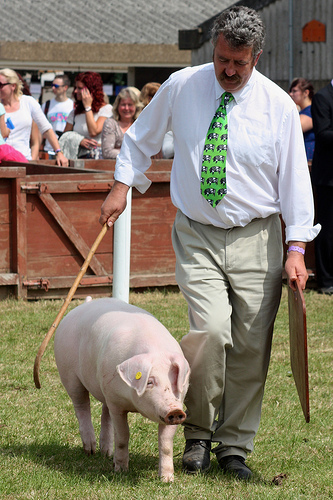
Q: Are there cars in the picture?
A: No, there are no cars.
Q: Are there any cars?
A: No, there are no cars.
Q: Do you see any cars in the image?
A: No, there are no cars.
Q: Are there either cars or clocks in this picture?
A: No, there are no cars or clocks.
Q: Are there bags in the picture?
A: No, there are no bags.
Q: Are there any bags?
A: No, there are no bags.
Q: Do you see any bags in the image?
A: No, there are no bags.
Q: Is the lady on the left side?
A: Yes, the lady is on the left of the image.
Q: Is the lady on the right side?
A: No, the lady is on the left of the image.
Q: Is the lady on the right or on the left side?
A: The lady is on the left of the image.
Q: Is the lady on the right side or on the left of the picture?
A: The lady is on the left of the image.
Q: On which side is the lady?
A: The lady is on the left of the image.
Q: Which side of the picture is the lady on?
A: The lady is on the left of the image.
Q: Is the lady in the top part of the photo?
A: Yes, the lady is in the top of the image.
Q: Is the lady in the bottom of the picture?
A: No, the lady is in the top of the image.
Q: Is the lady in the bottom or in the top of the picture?
A: The lady is in the top of the image.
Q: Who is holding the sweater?
A: The lady is holding the sweater.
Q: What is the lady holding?
A: The lady is holding the sweater.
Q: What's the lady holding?
A: The lady is holding the sweater.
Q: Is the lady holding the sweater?
A: Yes, the lady is holding the sweater.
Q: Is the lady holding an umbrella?
A: No, the lady is holding the sweater.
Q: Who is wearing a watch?
A: The lady is wearing a watch.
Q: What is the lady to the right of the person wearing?
A: The lady is wearing a watch.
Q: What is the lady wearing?
A: The lady is wearing a watch.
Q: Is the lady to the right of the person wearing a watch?
A: Yes, the lady is wearing a watch.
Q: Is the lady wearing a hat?
A: No, the lady is wearing a watch.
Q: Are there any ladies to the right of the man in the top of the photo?
A: Yes, there is a lady to the right of the man.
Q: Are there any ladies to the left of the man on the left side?
A: No, the lady is to the right of the man.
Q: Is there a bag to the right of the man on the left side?
A: No, there is a lady to the right of the man.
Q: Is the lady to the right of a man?
A: Yes, the lady is to the right of a man.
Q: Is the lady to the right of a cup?
A: No, the lady is to the right of a man.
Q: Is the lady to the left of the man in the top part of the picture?
A: No, the lady is to the right of the man.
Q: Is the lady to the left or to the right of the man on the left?
A: The lady is to the right of the man.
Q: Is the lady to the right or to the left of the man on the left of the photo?
A: The lady is to the right of the man.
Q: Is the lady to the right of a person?
A: Yes, the lady is to the right of a person.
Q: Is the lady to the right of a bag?
A: No, the lady is to the right of a person.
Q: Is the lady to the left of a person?
A: No, the lady is to the right of a person.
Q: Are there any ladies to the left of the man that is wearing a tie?
A: Yes, there is a lady to the left of the man.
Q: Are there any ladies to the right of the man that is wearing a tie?
A: No, the lady is to the left of the man.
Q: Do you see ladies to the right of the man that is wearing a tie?
A: No, the lady is to the left of the man.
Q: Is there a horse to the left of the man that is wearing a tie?
A: No, there is a lady to the left of the man.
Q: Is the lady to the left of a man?
A: Yes, the lady is to the left of a man.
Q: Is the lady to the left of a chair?
A: No, the lady is to the left of a man.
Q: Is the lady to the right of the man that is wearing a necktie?
A: No, the lady is to the left of the man.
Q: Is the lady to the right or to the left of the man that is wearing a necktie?
A: The lady is to the left of the man.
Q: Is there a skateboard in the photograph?
A: No, there are no skateboards.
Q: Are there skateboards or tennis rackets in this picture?
A: No, there are no skateboards or tennis rackets.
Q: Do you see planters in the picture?
A: No, there are no planters.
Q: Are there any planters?
A: No, there are no planters.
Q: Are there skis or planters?
A: No, there are no planters or skis.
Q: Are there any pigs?
A: Yes, there is a pig.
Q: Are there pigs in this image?
A: Yes, there is a pig.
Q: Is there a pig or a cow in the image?
A: Yes, there is a pig.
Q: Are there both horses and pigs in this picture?
A: No, there is a pig but no horses.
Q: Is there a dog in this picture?
A: No, there are no dogs.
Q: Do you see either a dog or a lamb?
A: No, there are no dogs or lambs.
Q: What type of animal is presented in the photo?
A: The animal is a pig.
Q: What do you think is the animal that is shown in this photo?
A: The animal is a pig.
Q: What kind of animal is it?
A: The animal is a pig.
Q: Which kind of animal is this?
A: That is a pig.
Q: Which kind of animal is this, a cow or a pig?
A: That is a pig.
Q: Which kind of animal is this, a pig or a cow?
A: That is a pig.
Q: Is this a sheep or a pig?
A: This is a pig.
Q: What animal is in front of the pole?
A: The pig is in front of the pole.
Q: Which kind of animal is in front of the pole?
A: The animal is a pig.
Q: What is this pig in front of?
A: The pig is in front of the pole.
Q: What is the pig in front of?
A: The pig is in front of the pole.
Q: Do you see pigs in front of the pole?
A: Yes, there is a pig in front of the pole.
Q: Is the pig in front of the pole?
A: Yes, the pig is in front of the pole.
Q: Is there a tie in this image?
A: Yes, there is a tie.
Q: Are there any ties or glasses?
A: Yes, there is a tie.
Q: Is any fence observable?
A: Yes, there is a fence.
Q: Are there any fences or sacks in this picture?
A: Yes, there is a fence.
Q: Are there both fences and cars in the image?
A: No, there is a fence but no cars.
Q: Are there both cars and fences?
A: No, there is a fence but no cars.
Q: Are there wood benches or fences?
A: Yes, there is a wood fence.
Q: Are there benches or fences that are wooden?
A: Yes, the fence is wooden.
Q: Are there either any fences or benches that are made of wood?
A: Yes, the fence is made of wood.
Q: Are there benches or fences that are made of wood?
A: Yes, the fence is made of wood.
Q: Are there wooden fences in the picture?
A: Yes, there is a wood fence.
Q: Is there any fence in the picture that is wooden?
A: Yes, there is a fence that is wooden.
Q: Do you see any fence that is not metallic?
A: Yes, there is a wooden fence.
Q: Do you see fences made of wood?
A: Yes, there is a fence that is made of wood.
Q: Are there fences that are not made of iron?
A: Yes, there is a fence that is made of wood.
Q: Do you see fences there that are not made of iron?
A: Yes, there is a fence that is made of wood.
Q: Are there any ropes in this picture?
A: No, there are no ropes.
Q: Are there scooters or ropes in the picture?
A: No, there are no ropes or scooters.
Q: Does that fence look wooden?
A: Yes, the fence is wooden.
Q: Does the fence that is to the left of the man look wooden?
A: Yes, the fence is wooden.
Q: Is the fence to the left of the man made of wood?
A: Yes, the fence is made of wood.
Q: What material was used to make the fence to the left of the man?
A: The fence is made of wood.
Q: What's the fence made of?
A: The fence is made of wood.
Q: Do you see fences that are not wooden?
A: No, there is a fence but it is wooden.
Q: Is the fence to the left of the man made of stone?
A: No, the fence is made of wood.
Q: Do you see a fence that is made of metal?
A: No, there is a fence but it is made of wood.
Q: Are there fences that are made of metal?
A: No, there is a fence but it is made of wood.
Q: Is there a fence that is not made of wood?
A: No, there is a fence but it is made of wood.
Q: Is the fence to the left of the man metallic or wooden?
A: The fence is wooden.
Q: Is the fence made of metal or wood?
A: The fence is made of wood.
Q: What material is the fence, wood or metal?
A: The fence is made of wood.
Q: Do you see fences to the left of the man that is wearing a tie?
A: Yes, there is a fence to the left of the man.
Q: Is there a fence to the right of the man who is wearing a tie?
A: No, the fence is to the left of the man.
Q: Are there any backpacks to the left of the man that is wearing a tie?
A: No, there is a fence to the left of the man.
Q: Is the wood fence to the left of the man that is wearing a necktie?
A: Yes, the fence is to the left of the man.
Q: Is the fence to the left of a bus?
A: No, the fence is to the left of the man.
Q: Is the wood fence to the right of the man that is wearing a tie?
A: No, the fence is to the left of the man.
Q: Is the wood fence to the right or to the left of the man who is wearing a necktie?
A: The fence is to the left of the man.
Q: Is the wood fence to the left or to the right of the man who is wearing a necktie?
A: The fence is to the left of the man.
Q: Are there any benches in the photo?
A: No, there are no benches.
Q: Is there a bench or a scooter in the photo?
A: No, there are no benches or scooters.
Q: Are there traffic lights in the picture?
A: No, there are no traffic lights.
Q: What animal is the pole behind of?
A: The pole is behind the pig.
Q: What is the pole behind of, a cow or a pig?
A: The pole is behind a pig.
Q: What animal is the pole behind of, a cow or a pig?
A: The pole is behind a pig.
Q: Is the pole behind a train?
A: No, the pole is behind a pig.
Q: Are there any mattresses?
A: No, there are no mattresses.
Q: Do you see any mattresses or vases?
A: No, there are no mattresses or vases.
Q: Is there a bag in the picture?
A: No, there are no bags.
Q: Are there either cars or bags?
A: No, there are no bags or cars.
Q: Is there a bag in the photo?
A: No, there are no bags.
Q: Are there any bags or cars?
A: No, there are no bags or cars.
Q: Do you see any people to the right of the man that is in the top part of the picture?
A: Yes, there is a person to the right of the man.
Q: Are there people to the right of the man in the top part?
A: Yes, there is a person to the right of the man.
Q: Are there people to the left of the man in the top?
A: No, the person is to the right of the man.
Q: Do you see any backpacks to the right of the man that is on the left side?
A: No, there is a person to the right of the man.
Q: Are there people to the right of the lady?
A: Yes, there is a person to the right of the lady.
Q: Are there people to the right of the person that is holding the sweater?
A: Yes, there is a person to the right of the lady.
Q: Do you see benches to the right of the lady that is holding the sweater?
A: No, there is a person to the right of the lady.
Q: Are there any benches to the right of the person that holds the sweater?
A: No, there is a person to the right of the lady.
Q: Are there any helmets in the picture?
A: No, there are no helmets.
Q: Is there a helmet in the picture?
A: No, there are no helmets.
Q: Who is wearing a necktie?
A: The man is wearing a necktie.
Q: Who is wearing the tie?
A: The man is wearing a necktie.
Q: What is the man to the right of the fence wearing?
A: The man is wearing a tie.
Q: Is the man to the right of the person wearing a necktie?
A: Yes, the man is wearing a necktie.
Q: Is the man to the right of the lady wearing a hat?
A: No, the man is wearing a necktie.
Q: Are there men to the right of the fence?
A: Yes, there is a man to the right of the fence.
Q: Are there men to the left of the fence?
A: No, the man is to the right of the fence.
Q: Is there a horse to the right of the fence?
A: No, there is a man to the right of the fence.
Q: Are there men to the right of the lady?
A: Yes, there is a man to the right of the lady.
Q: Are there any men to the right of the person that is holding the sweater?
A: Yes, there is a man to the right of the lady.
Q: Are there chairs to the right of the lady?
A: No, there is a man to the right of the lady.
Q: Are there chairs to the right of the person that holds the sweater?
A: No, there is a man to the right of the lady.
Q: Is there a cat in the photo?
A: No, there are no cats.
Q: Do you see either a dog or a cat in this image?
A: No, there are no cats or dogs.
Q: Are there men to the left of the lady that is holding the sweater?
A: Yes, there is a man to the left of the lady.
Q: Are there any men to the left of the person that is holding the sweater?
A: Yes, there is a man to the left of the lady.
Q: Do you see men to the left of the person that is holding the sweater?
A: Yes, there is a man to the left of the lady.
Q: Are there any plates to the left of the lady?
A: No, there is a man to the left of the lady.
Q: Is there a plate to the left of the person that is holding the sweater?
A: No, there is a man to the left of the lady.